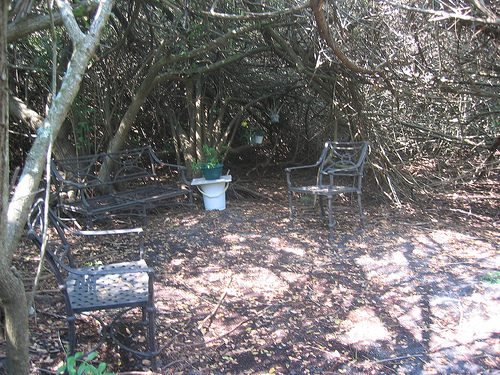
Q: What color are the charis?
A: Black.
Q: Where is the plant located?
A: Next to the bench.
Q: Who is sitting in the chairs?
A: No one.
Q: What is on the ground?
A: Shadows.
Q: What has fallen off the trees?
A: Leafs.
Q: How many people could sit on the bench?
A: Two.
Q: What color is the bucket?
A: White.